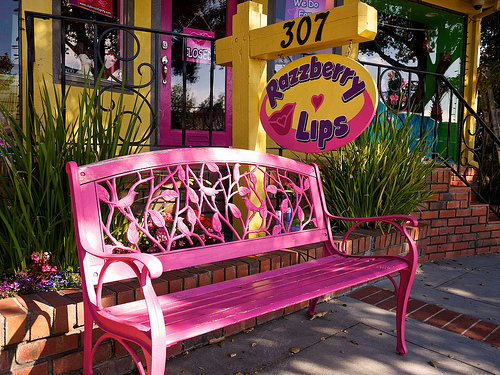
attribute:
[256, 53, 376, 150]
sign — pink, yellow, purple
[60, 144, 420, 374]
bench — patterned, is empty, in the distance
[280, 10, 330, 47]
number — on belt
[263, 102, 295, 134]
lips — pink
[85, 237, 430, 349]
bench seat — wood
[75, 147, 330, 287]
back — metal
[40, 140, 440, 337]
bench — is pink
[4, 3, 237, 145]
building — colorful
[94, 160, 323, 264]
pattern — floral